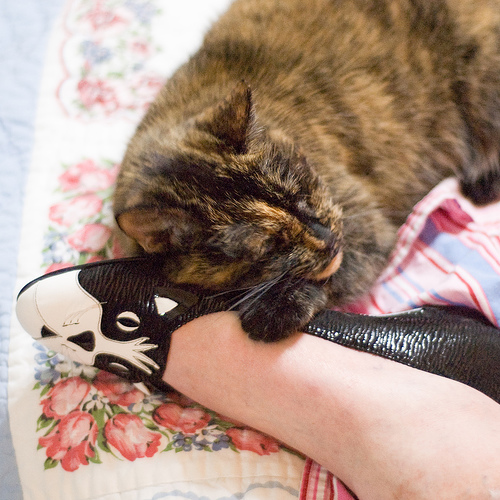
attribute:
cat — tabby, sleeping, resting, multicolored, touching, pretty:
[119, 2, 499, 345]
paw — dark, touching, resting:
[239, 276, 331, 343]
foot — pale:
[20, 247, 498, 499]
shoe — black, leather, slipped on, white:
[19, 247, 498, 399]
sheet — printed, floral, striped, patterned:
[4, 1, 178, 284]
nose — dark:
[302, 225, 335, 247]